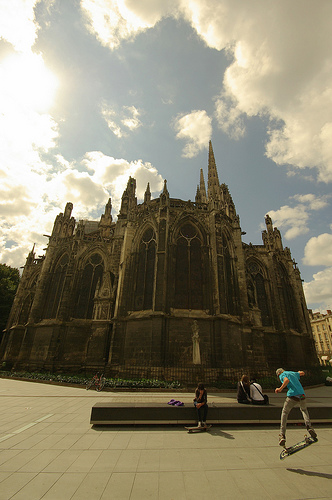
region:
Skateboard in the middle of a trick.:
[273, 429, 331, 465]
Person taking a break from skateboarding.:
[179, 373, 225, 440]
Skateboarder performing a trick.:
[264, 367, 326, 470]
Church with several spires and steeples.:
[19, 138, 320, 393]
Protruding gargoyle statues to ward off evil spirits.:
[37, 226, 55, 261]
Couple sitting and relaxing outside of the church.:
[229, 359, 275, 421]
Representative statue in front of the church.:
[185, 312, 210, 374]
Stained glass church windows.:
[170, 218, 215, 327]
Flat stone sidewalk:
[5, 381, 121, 492]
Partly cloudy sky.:
[3, 3, 327, 156]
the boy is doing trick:
[277, 367, 313, 452]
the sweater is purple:
[167, 396, 183, 407]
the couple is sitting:
[229, 372, 269, 407]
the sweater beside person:
[160, 376, 214, 438]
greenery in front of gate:
[24, 370, 83, 386]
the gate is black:
[117, 320, 271, 368]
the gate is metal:
[110, 322, 240, 363]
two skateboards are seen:
[184, 416, 324, 477]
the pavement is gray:
[63, 439, 285, 489]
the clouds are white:
[13, 51, 287, 159]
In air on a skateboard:
[254, 354, 330, 481]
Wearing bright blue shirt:
[255, 350, 323, 429]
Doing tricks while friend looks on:
[172, 362, 330, 470]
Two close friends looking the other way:
[225, 361, 296, 426]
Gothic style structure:
[3, 159, 327, 376]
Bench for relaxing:
[83, 364, 331, 444]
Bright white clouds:
[2, 157, 187, 274]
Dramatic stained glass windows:
[159, 168, 244, 349]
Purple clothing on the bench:
[159, 390, 198, 411]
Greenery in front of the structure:
[2, 341, 197, 404]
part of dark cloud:
[277, 43, 293, 75]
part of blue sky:
[151, 58, 182, 80]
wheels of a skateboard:
[295, 444, 308, 447]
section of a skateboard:
[291, 440, 301, 452]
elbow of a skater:
[283, 379, 287, 385]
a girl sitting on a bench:
[198, 390, 207, 417]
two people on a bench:
[241, 382, 258, 395]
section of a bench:
[143, 407, 164, 410]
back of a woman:
[241, 383, 247, 392]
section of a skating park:
[146, 461, 179, 473]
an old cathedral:
[10, 142, 319, 387]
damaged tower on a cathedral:
[12, 183, 106, 327]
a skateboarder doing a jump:
[274, 356, 314, 464]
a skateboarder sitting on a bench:
[183, 380, 216, 432]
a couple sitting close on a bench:
[232, 367, 274, 405]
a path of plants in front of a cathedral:
[1, 363, 192, 399]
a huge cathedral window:
[167, 207, 218, 323]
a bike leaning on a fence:
[78, 367, 110, 395]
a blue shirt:
[270, 366, 317, 393]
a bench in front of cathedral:
[78, 389, 331, 457]